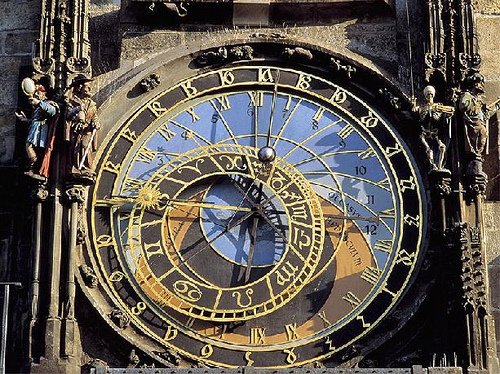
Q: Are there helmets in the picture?
A: No, there are no helmets.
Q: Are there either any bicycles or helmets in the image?
A: No, there are no helmets or bicycles.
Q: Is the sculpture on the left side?
A: Yes, the sculpture is on the left of the image.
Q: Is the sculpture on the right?
A: No, the sculpture is on the left of the image.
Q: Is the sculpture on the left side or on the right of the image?
A: The sculpture is on the left of the image.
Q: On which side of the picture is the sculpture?
A: The sculpture is on the left of the image.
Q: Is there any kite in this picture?
A: No, there are no kites.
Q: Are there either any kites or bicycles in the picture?
A: No, there are no kites or bicycles.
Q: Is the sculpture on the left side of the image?
A: Yes, the sculpture is on the left of the image.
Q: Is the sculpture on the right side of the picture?
A: No, the sculpture is on the left of the image.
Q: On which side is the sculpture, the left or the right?
A: The sculpture is on the left of the image.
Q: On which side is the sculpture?
A: The sculpture is on the left of the image.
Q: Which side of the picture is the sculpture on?
A: The sculpture is on the left of the image.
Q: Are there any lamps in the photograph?
A: No, there are no lamps.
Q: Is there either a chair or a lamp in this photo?
A: No, there are no lamps or chairs.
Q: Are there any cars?
A: No, there are no cars.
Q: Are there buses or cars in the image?
A: No, there are no cars or buses.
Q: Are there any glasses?
A: No, there are no glasses.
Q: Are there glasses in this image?
A: No, there are no glasses.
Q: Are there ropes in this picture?
A: No, there are no ropes.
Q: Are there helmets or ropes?
A: No, there are no ropes or helmets.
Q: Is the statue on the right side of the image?
A: Yes, the statue is on the right of the image.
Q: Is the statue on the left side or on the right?
A: The statue is on the right of the image.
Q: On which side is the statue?
A: The statue is on the right of the image.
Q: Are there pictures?
A: No, there are no pictures.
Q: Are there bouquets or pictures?
A: No, there are no pictures or bouquets.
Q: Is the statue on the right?
A: Yes, the statue is on the right of the image.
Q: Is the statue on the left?
A: No, the statue is on the right of the image.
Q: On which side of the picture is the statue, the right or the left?
A: The statue is on the right of the image.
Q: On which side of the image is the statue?
A: The statue is on the right of the image.